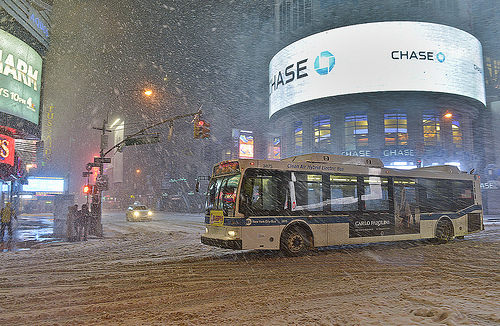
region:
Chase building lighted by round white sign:
[260, 10, 499, 152]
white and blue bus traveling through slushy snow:
[201, 152, 488, 255]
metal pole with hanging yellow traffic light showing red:
[94, 99, 213, 254]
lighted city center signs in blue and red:
[3, 5, 61, 166]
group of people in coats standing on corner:
[63, 195, 100, 240]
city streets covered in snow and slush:
[3, 193, 493, 315]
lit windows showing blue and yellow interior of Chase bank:
[277, 107, 472, 152]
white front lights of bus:
[200, 222, 242, 237]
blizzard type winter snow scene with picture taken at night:
[4, 5, 498, 319]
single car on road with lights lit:
[124, 200, 154, 227]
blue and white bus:
[183, 158, 492, 257]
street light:
[140, 106, 221, 142]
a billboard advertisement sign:
[263, 31, 496, 111]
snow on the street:
[45, 253, 420, 323]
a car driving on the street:
[122, 198, 162, 228]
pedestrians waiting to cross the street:
[64, 203, 95, 240]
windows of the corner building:
[293, 111, 467, 156]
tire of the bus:
[280, 227, 311, 257]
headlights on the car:
[128, 209, 155, 219]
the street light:
[134, 84, 167, 103]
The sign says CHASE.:
[386, 40, 450, 72]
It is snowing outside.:
[100, 38, 247, 115]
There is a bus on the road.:
[201, 150, 493, 259]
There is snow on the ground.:
[38, 255, 325, 318]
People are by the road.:
[54, 194, 99, 242]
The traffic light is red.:
[186, 113, 219, 142]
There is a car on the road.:
[121, 202, 162, 233]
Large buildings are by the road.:
[2, 7, 43, 264]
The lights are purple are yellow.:
[287, 108, 474, 155]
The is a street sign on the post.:
[104, 129, 181, 151]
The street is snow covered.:
[1, 196, 498, 323]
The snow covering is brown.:
[0, 188, 499, 324]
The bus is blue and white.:
[186, 142, 499, 259]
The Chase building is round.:
[259, 1, 494, 242]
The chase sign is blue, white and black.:
[253, 15, 496, 125]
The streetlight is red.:
[76, 176, 101, 206]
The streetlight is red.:
[188, 106, 211, 143]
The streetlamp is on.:
[98, 74, 158, 229]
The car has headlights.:
[117, 198, 174, 240]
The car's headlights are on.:
[113, 193, 168, 237]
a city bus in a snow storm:
[156, 80, 493, 276]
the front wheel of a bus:
[276, 218, 314, 256]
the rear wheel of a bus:
[431, 212, 456, 241]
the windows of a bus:
[251, 169, 477, 214]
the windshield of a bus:
[208, 177, 240, 213]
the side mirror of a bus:
[190, 174, 205, 194]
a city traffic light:
[186, 109, 214, 141]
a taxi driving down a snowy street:
[120, 197, 186, 239]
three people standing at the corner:
[62, 198, 97, 243]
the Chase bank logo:
[311, 48, 338, 78]